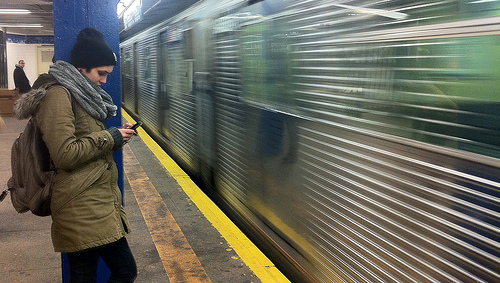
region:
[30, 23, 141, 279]
person in brown jacket looking at phone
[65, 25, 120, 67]
black knit hat on person's head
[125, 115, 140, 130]
cellphone in person's hand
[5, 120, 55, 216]
brown backpack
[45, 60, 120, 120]
grey scarf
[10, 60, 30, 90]
man with black jacket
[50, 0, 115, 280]
blue support beam person is leaning against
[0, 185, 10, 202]
zipper on brown backpack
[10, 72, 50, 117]
furry hood on brown jacket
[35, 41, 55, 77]
off-white door in background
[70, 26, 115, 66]
Black hat on a girl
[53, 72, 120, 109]
Gray scarf around a girl's neck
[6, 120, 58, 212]
Tan backpack on a girl's back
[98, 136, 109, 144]
A button on a girl's tan jacket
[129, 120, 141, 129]
A cell phone in a girl's hand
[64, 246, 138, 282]
Black pants on a girl's legs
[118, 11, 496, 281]
Silver subway train in front of the girl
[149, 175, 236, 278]
Yellow stripes on the subway platform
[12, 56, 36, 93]
A man in a black coat waiting for a train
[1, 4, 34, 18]
A light on the ceiling of the subway station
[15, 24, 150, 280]
Young lady with a cell phone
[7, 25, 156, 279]
Woman with black pants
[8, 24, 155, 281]
Lady with green backpack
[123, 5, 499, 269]
Subway passing in front of lady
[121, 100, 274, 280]
Yellow line in sidewalk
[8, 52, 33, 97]
Man wearing glasses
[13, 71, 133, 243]
Green jacket with hood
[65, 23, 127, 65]
Black cap on head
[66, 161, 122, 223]
Pocket of green jacket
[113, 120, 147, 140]
Cell phone on hands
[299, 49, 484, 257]
silver train speeding by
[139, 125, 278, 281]
cautionary yellow line in the station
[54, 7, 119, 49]
a blue pillar in the station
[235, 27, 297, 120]
a window on the tram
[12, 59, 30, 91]
a man in dark clothes in the backdrop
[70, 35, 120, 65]
dark blue hat on the woman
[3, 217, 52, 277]
the cement floor of the station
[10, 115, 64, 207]
the womans backpack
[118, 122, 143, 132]
the womans cell phone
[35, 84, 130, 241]
the womans tan coat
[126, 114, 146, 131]
black cell phone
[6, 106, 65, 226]
dark green back pack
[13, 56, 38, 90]
man in black coat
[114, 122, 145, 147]
girls fingers punching on cell phone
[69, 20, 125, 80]
girl wearing black wool cap with white speck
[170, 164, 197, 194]
portion of yellow edge line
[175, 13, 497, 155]
portion of speeding silver train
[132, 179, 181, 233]
portion of wide orange line caked with dirt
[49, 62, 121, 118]
girl wearing tan scarf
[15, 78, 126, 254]
girl wearing green jacket with hood